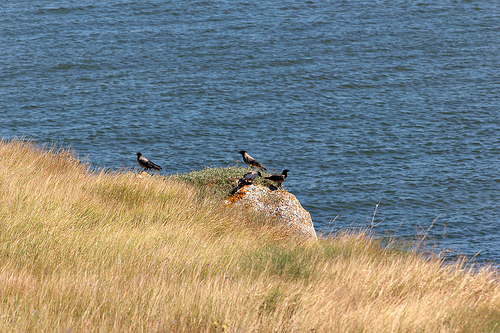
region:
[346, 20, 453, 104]
ripples on the water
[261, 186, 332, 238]
rock on the water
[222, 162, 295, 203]
birds on the rock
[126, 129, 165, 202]
bird on the perch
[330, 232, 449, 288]
grass along the water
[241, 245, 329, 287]
blades of grass in field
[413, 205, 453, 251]
blade of grass over water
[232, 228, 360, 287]
patch of green grass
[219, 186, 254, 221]
lichen on the rock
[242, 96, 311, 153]
body of the water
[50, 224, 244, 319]
brown and green meadow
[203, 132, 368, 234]
three birds on a rock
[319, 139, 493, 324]
edge of cliff and water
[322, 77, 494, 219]
water with rippling waves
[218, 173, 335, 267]
reddish orange spots on a rock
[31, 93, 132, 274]
edge of a cliff over water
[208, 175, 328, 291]
rock at edge of a meadow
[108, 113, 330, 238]
four black birds standing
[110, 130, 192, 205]
black bird with white back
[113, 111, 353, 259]
four birds not flying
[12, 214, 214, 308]
brown grasses near water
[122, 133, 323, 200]
birds perched on a rock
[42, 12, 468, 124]
blue waters of an ocean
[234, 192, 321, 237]
boulder in the grass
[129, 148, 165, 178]
black and grey bird standing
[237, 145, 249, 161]
head of a bird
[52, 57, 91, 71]
ripple in the water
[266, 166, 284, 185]
wing of a bird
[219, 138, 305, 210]
three birds on a rock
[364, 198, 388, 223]
tall brown grass near water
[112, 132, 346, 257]
plenty birds are visible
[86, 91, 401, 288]
plenty birds are visible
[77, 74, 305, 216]
plenty birds are visible